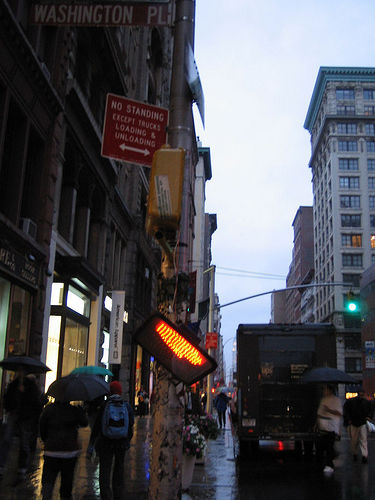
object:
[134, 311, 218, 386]
crosswalk sign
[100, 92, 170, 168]
sign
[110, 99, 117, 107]
letters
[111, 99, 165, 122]
no standing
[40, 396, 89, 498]
person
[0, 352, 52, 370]
umbrella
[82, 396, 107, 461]
person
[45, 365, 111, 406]
umbrella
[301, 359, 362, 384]
umbrella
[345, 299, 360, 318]
traffic light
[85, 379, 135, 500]
person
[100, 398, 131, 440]
backpack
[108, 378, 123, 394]
hat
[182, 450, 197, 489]
pot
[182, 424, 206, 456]
flowers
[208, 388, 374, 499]
street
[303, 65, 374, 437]
building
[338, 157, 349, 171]
window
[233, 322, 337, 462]
vehicle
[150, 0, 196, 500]
pole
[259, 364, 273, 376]
ups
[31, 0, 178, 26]
sign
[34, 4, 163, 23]
washington pl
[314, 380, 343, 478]
pedestrian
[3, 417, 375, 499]
pavement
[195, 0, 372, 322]
sky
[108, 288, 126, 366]
banner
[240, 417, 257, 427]
license plate